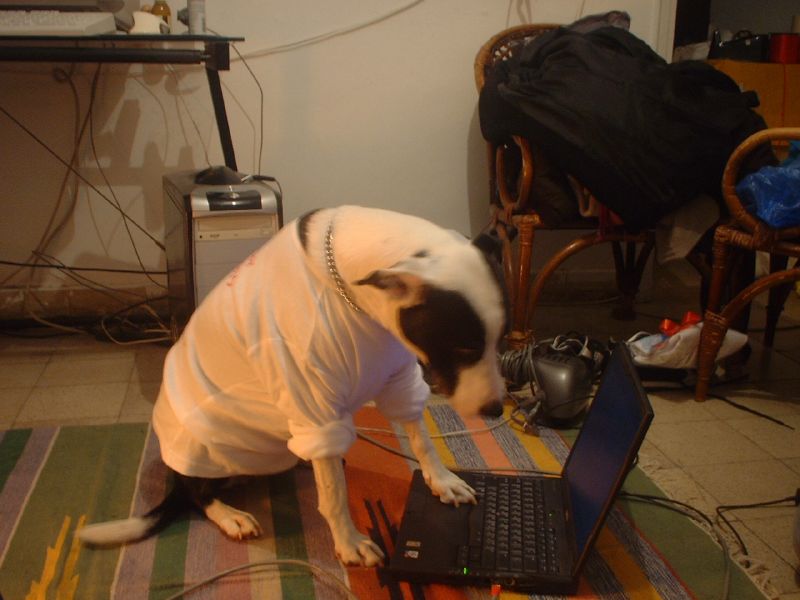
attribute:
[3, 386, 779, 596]
area rug — multi colored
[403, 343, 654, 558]
laptop — BLACK, OPEN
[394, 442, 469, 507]
paw — DOG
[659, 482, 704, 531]
cords — BLACK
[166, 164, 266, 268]
case — COMPUTER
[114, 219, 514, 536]
dog — WHITE, BLACK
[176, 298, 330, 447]
shirt — TEE, WHITE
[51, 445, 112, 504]
rug — COLORFUL, LARGE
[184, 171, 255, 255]
drive — HARD, COMPUTER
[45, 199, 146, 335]
wires — WHOLE, BUNCH, COMPUTER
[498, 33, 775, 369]
chairs — WICKER, STYLE